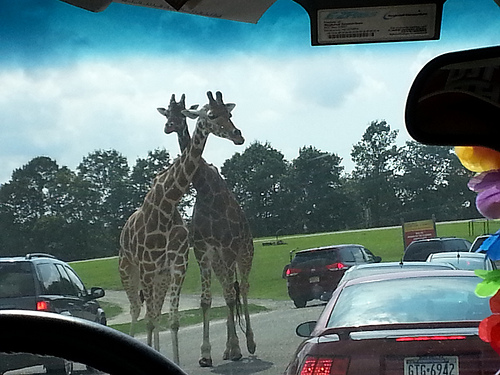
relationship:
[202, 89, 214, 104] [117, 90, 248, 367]
horns on giraffe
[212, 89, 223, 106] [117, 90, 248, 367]
horns on giraffe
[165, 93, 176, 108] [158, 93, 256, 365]
horns on giraffe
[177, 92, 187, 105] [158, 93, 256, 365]
horns on giraffe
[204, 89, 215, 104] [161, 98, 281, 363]
horns on giraffe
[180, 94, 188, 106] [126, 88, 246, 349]
horns on giraffe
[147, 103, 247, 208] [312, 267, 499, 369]
giraffe walking around car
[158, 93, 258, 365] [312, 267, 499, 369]
giraffe walking around car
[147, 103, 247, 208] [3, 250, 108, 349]
giraffe walking around car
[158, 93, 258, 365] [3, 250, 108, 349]
giraffe walking around car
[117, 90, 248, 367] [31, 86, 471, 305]
giraffe in reserve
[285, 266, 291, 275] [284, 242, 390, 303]
light on car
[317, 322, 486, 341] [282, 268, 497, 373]
spoiler on car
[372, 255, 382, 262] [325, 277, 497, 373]
mirror siding car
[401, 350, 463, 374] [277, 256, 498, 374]
license plate of car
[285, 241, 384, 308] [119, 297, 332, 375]
car parked by ground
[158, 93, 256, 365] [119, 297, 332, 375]
giraffe on ground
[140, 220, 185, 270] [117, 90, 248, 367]
spots on giraffe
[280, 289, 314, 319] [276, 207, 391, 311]
wheel on car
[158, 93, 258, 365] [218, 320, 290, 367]
giraffe in road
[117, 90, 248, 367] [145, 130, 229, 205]
giraffe has necks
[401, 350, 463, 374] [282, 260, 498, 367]
license plate on car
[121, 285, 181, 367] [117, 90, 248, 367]
legs of giraffe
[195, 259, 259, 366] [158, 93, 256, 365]
legs of giraffe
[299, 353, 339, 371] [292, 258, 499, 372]
light on car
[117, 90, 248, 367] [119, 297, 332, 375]
giraffe are on ground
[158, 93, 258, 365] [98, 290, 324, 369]
giraffe in road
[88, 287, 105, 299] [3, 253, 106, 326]
mirror on car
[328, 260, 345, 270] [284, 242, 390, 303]
brake light on car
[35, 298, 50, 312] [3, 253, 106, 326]
light on car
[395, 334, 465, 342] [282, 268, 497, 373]
brake light on car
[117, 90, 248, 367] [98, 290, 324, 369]
giraffe are in road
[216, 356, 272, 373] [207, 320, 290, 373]
shadow on ground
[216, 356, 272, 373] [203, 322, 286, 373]
shadow on ground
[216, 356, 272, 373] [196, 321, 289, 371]
shadow on ground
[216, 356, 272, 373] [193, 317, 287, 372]
shadow on ground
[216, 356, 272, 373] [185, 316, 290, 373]
shadow on ground